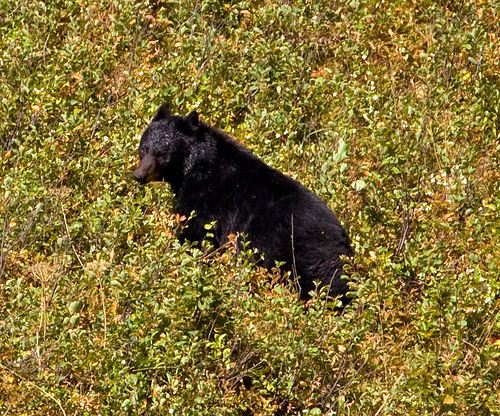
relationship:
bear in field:
[133, 94, 351, 315] [1, 3, 484, 413]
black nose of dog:
[129, 164, 147, 184] [134, 100, 355, 312]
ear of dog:
[151, 97, 178, 119] [134, 100, 355, 312]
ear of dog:
[185, 106, 202, 123] [134, 100, 355, 312]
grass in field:
[104, 255, 314, 368] [1, 3, 484, 413]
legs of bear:
[172, 197, 207, 243] [133, 94, 351, 315]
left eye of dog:
[161, 152, 170, 160] [134, 100, 355, 312]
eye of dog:
[137, 145, 147, 156] [124, 95, 347, 308]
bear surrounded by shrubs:
[133, 94, 351, 315] [2, 87, 496, 409]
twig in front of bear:
[285, 212, 315, 290] [159, 117, 359, 269]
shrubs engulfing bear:
[0, 0, 500, 408] [121, 95, 372, 303]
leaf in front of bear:
[201, 222, 213, 231] [133, 90, 351, 311]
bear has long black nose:
[133, 94, 351, 315] [129, 164, 147, 184]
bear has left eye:
[133, 94, 351, 315] [161, 152, 170, 160]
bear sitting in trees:
[133, 94, 351, 315] [16, 234, 282, 406]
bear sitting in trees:
[133, 90, 351, 311] [80, 301, 260, 403]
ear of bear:
[153, 97, 171, 120] [133, 94, 351, 315]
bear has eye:
[133, 94, 351, 315] [135, 138, 152, 158]